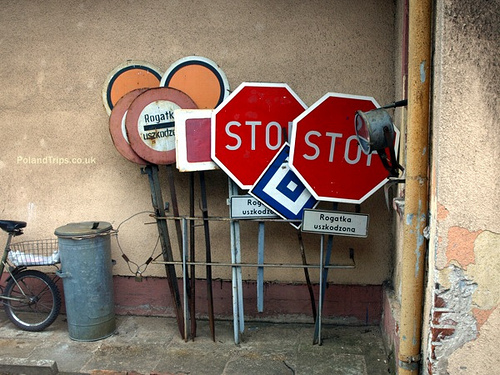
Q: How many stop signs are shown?
A: 2.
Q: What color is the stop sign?
A: Red.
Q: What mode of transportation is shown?
A: Bicycle.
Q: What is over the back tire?
A: Basket.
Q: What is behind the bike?
A: Trash can.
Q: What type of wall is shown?
A: Concrete.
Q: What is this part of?
A: Wall.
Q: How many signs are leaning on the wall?
A: Ten.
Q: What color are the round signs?
A: Orange.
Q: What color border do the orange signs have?
A: White.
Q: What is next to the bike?
A: Trash can.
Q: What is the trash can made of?
A: Metal.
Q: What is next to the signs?
A: A trash can.